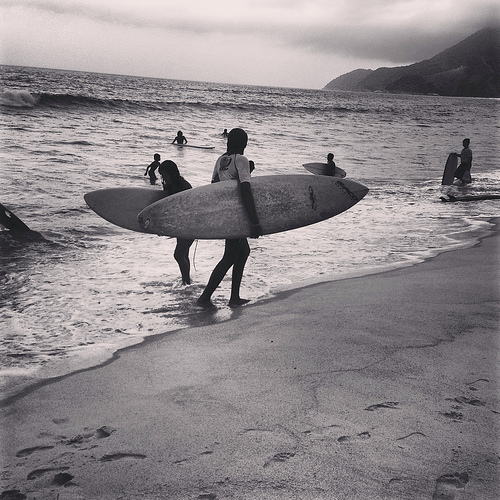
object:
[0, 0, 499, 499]
scene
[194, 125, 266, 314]
person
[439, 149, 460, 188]
surfboard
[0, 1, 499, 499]
background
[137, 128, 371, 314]
surf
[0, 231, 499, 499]
beach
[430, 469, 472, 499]
footprint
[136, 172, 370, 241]
surfboard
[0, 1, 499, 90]
sky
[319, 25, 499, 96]
mountain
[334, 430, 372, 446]
footprint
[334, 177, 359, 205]
writing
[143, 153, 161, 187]
child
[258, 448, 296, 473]
footprint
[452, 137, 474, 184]
man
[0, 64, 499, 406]
ocean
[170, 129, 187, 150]
man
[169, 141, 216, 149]
surfboard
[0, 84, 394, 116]
wave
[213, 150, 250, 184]
swim shirt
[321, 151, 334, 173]
man